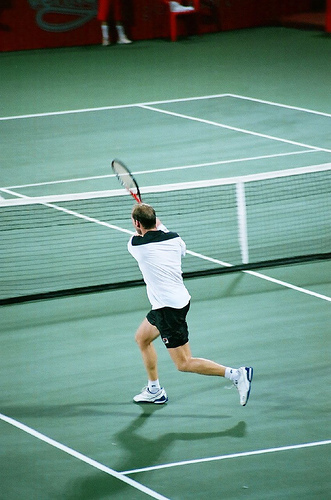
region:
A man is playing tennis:
[105, 152, 260, 413]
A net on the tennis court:
[0, 157, 326, 303]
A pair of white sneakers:
[129, 360, 252, 406]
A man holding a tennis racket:
[105, 152, 188, 257]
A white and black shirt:
[122, 224, 190, 309]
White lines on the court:
[0, 89, 326, 493]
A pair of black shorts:
[139, 292, 192, 349]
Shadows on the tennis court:
[0, 388, 245, 493]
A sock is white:
[220, 361, 238, 385]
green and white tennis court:
[4, 3, 329, 493]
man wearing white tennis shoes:
[131, 365, 254, 405]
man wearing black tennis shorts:
[145, 301, 192, 361]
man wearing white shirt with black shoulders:
[127, 221, 194, 310]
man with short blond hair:
[130, 201, 158, 231]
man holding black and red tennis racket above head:
[108, 155, 147, 217]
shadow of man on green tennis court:
[54, 408, 259, 495]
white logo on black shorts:
[161, 338, 167, 345]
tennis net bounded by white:
[2, 158, 330, 306]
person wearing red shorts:
[97, 2, 124, 28]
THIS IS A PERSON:
[111, 201, 281, 422]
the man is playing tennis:
[81, 147, 302, 445]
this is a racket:
[103, 153, 172, 241]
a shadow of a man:
[73, 406, 251, 496]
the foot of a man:
[154, 320, 275, 408]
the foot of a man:
[113, 300, 176, 417]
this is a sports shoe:
[111, 374, 177, 424]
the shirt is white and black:
[117, 229, 210, 316]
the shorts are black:
[136, 299, 201, 358]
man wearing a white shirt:
[124, 229, 190, 307]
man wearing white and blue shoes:
[129, 387, 168, 403]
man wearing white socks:
[143, 376, 161, 391]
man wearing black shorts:
[135, 296, 200, 351]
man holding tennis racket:
[108, 154, 255, 440]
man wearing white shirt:
[106, 163, 261, 423]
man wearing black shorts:
[107, 155, 267, 418]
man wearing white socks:
[107, 159, 282, 439]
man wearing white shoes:
[118, 160, 271, 421]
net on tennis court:
[198, 167, 294, 238]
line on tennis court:
[151, 449, 238, 470]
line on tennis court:
[22, 419, 71, 459]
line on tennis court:
[248, 272, 302, 297]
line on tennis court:
[189, 106, 241, 135]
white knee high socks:
[100, 24, 131, 45]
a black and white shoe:
[132, 391, 166, 404]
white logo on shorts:
[160, 335, 169, 346]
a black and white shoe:
[228, 366, 248, 402]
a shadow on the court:
[49, 388, 252, 497]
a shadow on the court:
[0, 399, 233, 420]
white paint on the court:
[0, 405, 329, 495]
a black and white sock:
[145, 376, 159, 392]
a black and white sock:
[223, 364, 234, 378]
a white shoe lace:
[137, 384, 147, 392]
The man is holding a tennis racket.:
[112, 157, 150, 203]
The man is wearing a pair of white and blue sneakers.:
[121, 357, 256, 417]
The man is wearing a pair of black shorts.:
[134, 298, 198, 347]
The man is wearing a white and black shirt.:
[119, 227, 201, 310]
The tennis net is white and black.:
[0, 159, 330, 298]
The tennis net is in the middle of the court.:
[5, 166, 329, 289]